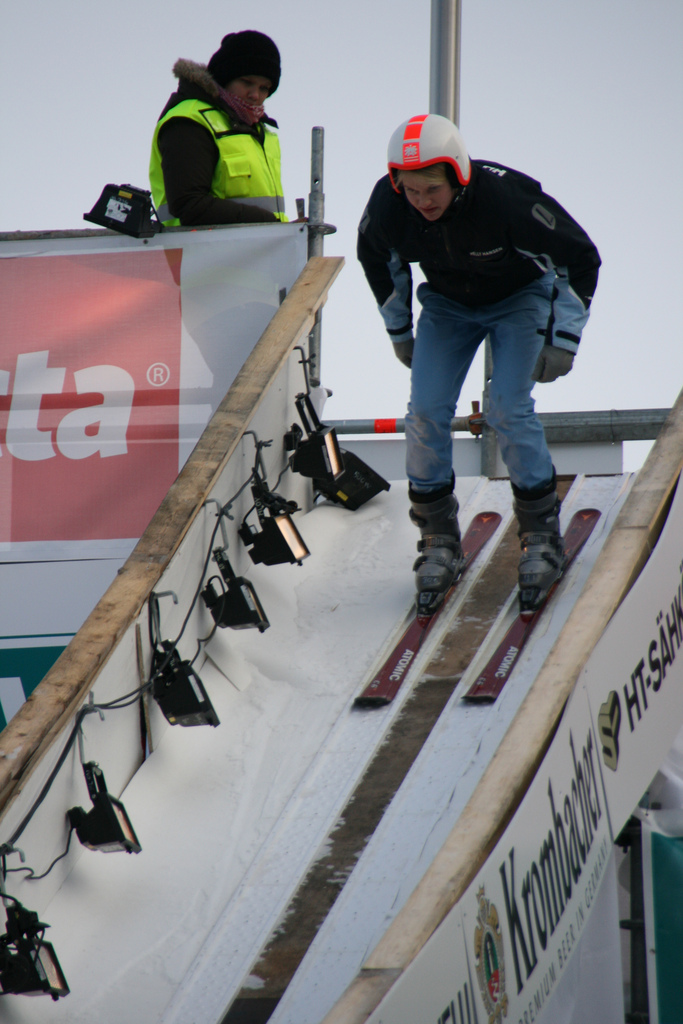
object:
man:
[354, 109, 602, 630]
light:
[277, 491, 324, 585]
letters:
[478, 719, 609, 1021]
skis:
[329, 444, 602, 746]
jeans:
[378, 288, 574, 513]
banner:
[414, 555, 680, 980]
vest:
[120, 93, 314, 231]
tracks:
[229, 692, 486, 989]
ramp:
[180, 425, 626, 891]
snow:
[240, 492, 359, 862]